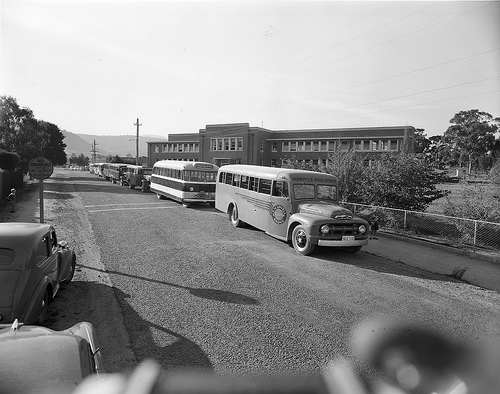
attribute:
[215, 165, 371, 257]
bus — grey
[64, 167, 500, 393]
street — dirt, tarmac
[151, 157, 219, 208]
bus — black, white, old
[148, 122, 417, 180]
building — photoed, old, brick, multi story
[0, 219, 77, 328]
car — small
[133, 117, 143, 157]
pole — electric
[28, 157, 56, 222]
sign — round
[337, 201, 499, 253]
fence — small, wire mesh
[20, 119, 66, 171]
tree — green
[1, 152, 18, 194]
tree — green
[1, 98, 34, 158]
tree — green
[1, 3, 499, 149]
sky — cloudy, hazy, grey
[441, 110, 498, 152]
tree — leaf filled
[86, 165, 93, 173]
bus — old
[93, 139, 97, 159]
pole — electric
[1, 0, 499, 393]
photo — black, white